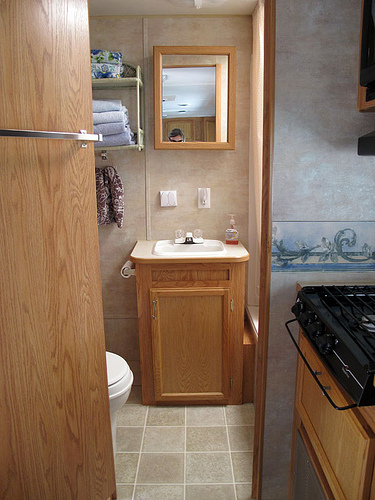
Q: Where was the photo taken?
A: It was taken at the bathroom.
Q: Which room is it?
A: It is a bathroom.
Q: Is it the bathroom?
A: Yes, it is the bathroom.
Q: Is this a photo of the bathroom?
A: Yes, it is showing the bathroom.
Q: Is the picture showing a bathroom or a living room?
A: It is showing a bathroom.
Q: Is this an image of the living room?
A: No, the picture is showing the bathroom.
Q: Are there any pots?
A: No, there are no pots.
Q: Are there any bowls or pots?
A: No, there are no pots or bowls.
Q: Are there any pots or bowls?
A: No, there are no pots or bowls.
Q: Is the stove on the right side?
A: Yes, the stove is on the right of the image.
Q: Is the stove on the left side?
A: No, the stove is on the right of the image.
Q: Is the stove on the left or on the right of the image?
A: The stove is on the right of the image.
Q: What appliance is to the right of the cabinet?
A: The appliance is a stove.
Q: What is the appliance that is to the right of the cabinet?
A: The appliance is a stove.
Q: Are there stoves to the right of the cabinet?
A: Yes, there is a stove to the right of the cabinet.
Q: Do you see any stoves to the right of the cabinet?
A: Yes, there is a stove to the right of the cabinet.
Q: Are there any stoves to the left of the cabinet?
A: No, the stove is to the right of the cabinet.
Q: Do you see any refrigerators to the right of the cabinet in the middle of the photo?
A: No, there is a stove to the right of the cabinet.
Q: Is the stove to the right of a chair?
A: No, the stove is to the right of the cabinet.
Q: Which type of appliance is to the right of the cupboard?
A: The appliance is a stove.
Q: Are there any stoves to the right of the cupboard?
A: Yes, there is a stove to the right of the cupboard.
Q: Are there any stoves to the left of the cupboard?
A: No, the stove is to the right of the cupboard.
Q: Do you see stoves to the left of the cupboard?
A: No, the stove is to the right of the cupboard.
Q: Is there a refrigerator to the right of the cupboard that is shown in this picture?
A: No, there is a stove to the right of the cupboard.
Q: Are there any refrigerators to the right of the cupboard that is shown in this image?
A: No, there is a stove to the right of the cupboard.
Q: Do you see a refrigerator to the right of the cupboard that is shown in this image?
A: No, there is a stove to the right of the cupboard.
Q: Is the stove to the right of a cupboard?
A: Yes, the stove is to the right of a cupboard.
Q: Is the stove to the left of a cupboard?
A: No, the stove is to the right of a cupboard.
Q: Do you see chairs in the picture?
A: No, there are no chairs.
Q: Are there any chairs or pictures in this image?
A: No, there are no chairs or pictures.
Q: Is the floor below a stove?
A: Yes, the floor is below a stove.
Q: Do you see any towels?
A: Yes, there is a towel.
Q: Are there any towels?
A: Yes, there is a towel.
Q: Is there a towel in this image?
A: Yes, there is a towel.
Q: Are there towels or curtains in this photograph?
A: Yes, there is a towel.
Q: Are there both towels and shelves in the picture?
A: Yes, there are both a towel and a shelf.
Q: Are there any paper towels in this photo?
A: No, there are no paper towels.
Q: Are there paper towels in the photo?
A: No, there are no paper towels.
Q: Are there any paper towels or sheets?
A: No, there are no paper towels or sheets.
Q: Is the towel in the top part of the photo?
A: Yes, the towel is in the top of the image.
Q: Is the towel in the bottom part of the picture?
A: No, the towel is in the top of the image.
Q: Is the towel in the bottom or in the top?
A: The towel is in the top of the image.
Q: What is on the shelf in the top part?
A: The towel is on the shelf.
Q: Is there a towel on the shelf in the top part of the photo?
A: Yes, there is a towel on the shelf.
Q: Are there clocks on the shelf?
A: No, there is a towel on the shelf.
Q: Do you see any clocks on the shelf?
A: No, there is a towel on the shelf.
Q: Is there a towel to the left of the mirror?
A: Yes, there is a towel to the left of the mirror.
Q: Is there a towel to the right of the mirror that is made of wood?
A: No, the towel is to the left of the mirror.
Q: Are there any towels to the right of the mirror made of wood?
A: No, the towel is to the left of the mirror.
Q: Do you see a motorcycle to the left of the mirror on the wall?
A: No, there is a towel to the left of the mirror.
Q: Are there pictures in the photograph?
A: No, there are no pictures.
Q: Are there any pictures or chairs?
A: No, there are no pictures or chairs.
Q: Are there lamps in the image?
A: No, there are no lamps.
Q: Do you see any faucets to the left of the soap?
A: Yes, there is a faucet to the left of the soap.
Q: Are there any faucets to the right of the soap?
A: No, the faucet is to the left of the soap.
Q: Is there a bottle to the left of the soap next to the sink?
A: No, there is a faucet to the left of the soap.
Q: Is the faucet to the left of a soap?
A: Yes, the faucet is to the left of a soap.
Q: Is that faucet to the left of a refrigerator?
A: No, the faucet is to the left of a soap.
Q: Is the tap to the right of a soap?
A: No, the tap is to the left of a soap.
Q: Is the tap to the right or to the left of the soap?
A: The tap is to the left of the soap.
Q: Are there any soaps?
A: Yes, there is a soap.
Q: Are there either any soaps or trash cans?
A: Yes, there is a soap.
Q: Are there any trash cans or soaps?
A: Yes, there is a soap.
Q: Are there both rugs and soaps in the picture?
A: No, there is a soap but no rugs.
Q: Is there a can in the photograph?
A: No, there are no cans.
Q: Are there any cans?
A: No, there are no cans.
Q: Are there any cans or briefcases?
A: No, there are no cans or briefcases.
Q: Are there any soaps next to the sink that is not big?
A: Yes, there is a soap next to the sink.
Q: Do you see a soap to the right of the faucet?
A: Yes, there is a soap to the right of the faucet.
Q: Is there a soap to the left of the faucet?
A: No, the soap is to the right of the faucet.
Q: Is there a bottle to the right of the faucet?
A: No, there is a soap to the right of the faucet.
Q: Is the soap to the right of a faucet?
A: Yes, the soap is to the right of a faucet.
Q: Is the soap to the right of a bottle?
A: No, the soap is to the right of a faucet.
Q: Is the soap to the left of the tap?
A: No, the soap is to the right of the tap.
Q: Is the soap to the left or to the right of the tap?
A: The soap is to the right of the tap.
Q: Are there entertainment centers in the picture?
A: No, there are no entertainment centers.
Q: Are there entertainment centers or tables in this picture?
A: No, there are no entertainment centers or tables.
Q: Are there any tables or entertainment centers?
A: No, there are no entertainment centers or tables.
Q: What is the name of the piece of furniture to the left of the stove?
A: The piece of furniture is a cupboard.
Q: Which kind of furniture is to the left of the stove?
A: The piece of furniture is a cupboard.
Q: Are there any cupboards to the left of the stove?
A: Yes, there is a cupboard to the left of the stove.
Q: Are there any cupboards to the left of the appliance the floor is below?
A: Yes, there is a cupboard to the left of the stove.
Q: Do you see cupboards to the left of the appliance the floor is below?
A: Yes, there is a cupboard to the left of the stove.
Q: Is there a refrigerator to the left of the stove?
A: No, there is a cupboard to the left of the stove.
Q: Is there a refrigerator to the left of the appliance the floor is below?
A: No, there is a cupboard to the left of the stove.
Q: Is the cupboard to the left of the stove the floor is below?
A: Yes, the cupboard is to the left of the stove.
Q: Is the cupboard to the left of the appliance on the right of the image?
A: Yes, the cupboard is to the left of the stove.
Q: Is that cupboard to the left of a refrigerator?
A: No, the cupboard is to the left of the stove.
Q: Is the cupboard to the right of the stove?
A: No, the cupboard is to the left of the stove.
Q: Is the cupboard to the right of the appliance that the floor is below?
A: No, the cupboard is to the left of the stove.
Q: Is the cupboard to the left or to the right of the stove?
A: The cupboard is to the left of the stove.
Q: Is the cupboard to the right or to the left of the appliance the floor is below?
A: The cupboard is to the left of the stove.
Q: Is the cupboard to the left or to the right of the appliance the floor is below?
A: The cupboard is to the left of the stove.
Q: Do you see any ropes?
A: No, there are no ropes.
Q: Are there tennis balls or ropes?
A: No, there are no ropes or tennis balls.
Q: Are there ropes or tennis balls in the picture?
A: No, there are no ropes or tennis balls.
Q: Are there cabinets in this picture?
A: Yes, there is a cabinet.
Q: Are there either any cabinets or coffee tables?
A: Yes, there is a cabinet.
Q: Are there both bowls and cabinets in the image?
A: No, there is a cabinet but no bowls.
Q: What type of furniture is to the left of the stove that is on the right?
A: The piece of furniture is a cabinet.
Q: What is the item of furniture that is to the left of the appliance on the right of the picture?
A: The piece of furniture is a cabinet.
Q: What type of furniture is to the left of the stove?
A: The piece of furniture is a cabinet.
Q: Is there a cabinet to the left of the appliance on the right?
A: Yes, there is a cabinet to the left of the stove.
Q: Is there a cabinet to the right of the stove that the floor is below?
A: No, the cabinet is to the left of the stove.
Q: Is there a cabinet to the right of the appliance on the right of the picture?
A: No, the cabinet is to the left of the stove.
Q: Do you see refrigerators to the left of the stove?
A: No, there is a cabinet to the left of the stove.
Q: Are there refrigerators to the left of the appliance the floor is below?
A: No, there is a cabinet to the left of the stove.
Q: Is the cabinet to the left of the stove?
A: Yes, the cabinet is to the left of the stove.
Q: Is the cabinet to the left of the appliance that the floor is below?
A: Yes, the cabinet is to the left of the stove.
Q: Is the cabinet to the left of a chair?
A: No, the cabinet is to the left of the stove.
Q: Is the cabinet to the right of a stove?
A: No, the cabinet is to the left of a stove.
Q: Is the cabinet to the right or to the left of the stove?
A: The cabinet is to the left of the stove.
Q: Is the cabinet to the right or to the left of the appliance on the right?
A: The cabinet is to the left of the stove.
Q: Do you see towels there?
A: Yes, there is a towel.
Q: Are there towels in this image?
A: Yes, there is a towel.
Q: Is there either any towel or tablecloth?
A: Yes, there is a towel.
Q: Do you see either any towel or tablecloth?
A: Yes, there is a towel.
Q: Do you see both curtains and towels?
A: No, there is a towel but no curtains.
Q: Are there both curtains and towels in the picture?
A: No, there is a towel but no curtains.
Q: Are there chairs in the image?
A: No, there are no chairs.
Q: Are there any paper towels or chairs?
A: No, there are no chairs or paper towels.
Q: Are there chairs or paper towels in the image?
A: No, there are no chairs or paper towels.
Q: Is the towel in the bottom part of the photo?
A: No, the towel is in the top of the image.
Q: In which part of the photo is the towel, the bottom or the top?
A: The towel is in the top of the image.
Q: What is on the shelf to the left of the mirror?
A: The towel is on the shelf.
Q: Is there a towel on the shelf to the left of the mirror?
A: Yes, there is a towel on the shelf.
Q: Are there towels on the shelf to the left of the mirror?
A: Yes, there is a towel on the shelf.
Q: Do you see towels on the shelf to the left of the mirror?
A: Yes, there is a towel on the shelf.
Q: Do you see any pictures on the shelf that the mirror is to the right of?
A: No, there is a towel on the shelf.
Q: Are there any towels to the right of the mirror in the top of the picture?
A: No, the towel is to the left of the mirror.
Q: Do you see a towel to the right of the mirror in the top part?
A: No, the towel is to the left of the mirror.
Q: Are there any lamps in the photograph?
A: No, there are no lamps.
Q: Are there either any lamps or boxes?
A: No, there are no lamps or boxes.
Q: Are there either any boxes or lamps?
A: No, there are no lamps or boxes.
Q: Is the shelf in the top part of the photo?
A: Yes, the shelf is in the top of the image.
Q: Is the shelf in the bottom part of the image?
A: No, the shelf is in the top of the image.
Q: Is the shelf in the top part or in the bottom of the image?
A: The shelf is in the top of the image.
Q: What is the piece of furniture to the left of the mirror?
A: The piece of furniture is a shelf.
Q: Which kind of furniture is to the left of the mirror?
A: The piece of furniture is a shelf.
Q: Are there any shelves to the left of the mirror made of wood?
A: Yes, there is a shelf to the left of the mirror.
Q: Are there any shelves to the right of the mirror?
A: No, the shelf is to the left of the mirror.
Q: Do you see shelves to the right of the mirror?
A: No, the shelf is to the left of the mirror.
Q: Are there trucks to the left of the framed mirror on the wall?
A: No, there is a shelf to the left of the mirror.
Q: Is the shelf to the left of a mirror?
A: Yes, the shelf is to the left of a mirror.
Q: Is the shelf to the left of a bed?
A: No, the shelf is to the left of a mirror.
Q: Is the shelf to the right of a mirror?
A: No, the shelf is to the left of a mirror.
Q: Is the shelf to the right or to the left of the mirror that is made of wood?
A: The shelf is to the left of the mirror.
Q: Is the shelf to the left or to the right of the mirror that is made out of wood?
A: The shelf is to the left of the mirror.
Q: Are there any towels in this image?
A: Yes, there is a towel.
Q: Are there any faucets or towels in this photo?
A: Yes, there is a towel.